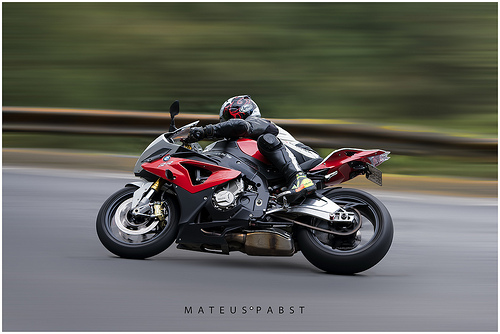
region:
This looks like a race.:
[58, 70, 473, 287]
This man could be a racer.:
[51, 52, 486, 262]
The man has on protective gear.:
[185, 101, 361, 225]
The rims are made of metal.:
[111, 186, 160, 238]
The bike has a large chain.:
[269, 198, 367, 245]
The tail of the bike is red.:
[304, 145, 401, 181]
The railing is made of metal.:
[8, 95, 159, 166]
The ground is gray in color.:
[7, 233, 112, 328]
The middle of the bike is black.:
[176, 192, 295, 235]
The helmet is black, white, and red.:
[218, 88, 270, 124]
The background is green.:
[18, 12, 164, 103]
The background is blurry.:
[20, 10, 484, 308]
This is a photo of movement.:
[31, 23, 457, 304]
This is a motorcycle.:
[103, 80, 439, 289]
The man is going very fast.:
[63, 46, 472, 307]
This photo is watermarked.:
[158, 275, 356, 322]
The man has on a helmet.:
[200, 83, 280, 129]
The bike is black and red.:
[137, 133, 385, 238]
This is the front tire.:
[92, 176, 200, 262]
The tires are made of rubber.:
[298, 233, 386, 269]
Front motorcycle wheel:
[94, 176, 177, 258]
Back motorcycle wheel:
[297, 185, 395, 274]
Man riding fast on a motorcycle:
[96, 90, 399, 278]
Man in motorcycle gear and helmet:
[180, 91, 323, 198]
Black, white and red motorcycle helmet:
[215, 93, 261, 120]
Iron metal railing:
[2, 100, 497, 167]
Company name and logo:
[180, 300, 309, 316]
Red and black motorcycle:
[91, 116, 394, 275]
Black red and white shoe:
[276, 171, 317, 200]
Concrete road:
[0, 153, 496, 331]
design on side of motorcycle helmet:
[221, 98, 251, 118]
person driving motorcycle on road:
[180, 80, 340, 215]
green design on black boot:
[280, 167, 316, 197]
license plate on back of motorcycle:
[355, 160, 385, 190]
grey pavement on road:
[5, 177, 90, 327]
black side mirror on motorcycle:
[155, 95, 185, 125]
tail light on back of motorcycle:
[365, 141, 395, 166]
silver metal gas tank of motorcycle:
[190, 211, 305, 272]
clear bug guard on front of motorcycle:
[156, 105, 198, 146]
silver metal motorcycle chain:
[275, 211, 328, 236]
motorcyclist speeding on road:
[88, 85, 395, 271]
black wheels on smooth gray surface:
[25, 215, 437, 300]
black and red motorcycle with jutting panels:
[128, 125, 386, 238]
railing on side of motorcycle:
[10, 100, 495, 160]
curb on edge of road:
[10, 135, 490, 200]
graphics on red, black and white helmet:
[217, 87, 257, 119]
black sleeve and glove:
[180, 115, 270, 140]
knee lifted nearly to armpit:
[182, 85, 319, 205]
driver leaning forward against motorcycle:
[181, 90, 316, 205]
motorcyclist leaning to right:
[95, 86, 395, 273]